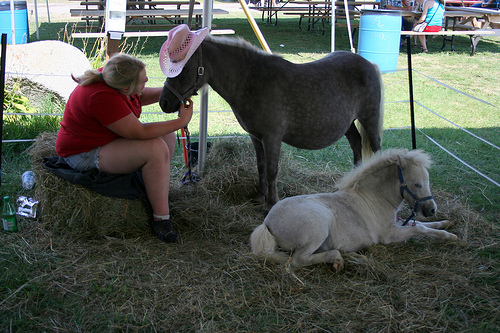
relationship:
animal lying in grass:
[250, 148, 457, 272] [80, 246, 498, 308]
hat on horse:
[156, 13, 212, 70] [190, 40, 383, 150]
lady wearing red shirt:
[54, 54, 192, 244] [69, 80, 123, 131]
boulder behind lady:
[3, 40, 91, 113] [67, 65, 161, 174]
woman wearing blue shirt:
[401, 0, 445, 52] [419, 6, 443, 24]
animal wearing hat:
[190, 46, 378, 163] [156, 24, 201, 64]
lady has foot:
[54, 54, 192, 244] [146, 204, 186, 240]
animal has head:
[261, 156, 439, 265] [369, 147, 441, 220]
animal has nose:
[250, 148, 457, 272] [406, 190, 447, 218]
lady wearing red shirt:
[61, 81, 174, 222] [66, 90, 123, 148]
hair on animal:
[208, 30, 254, 65] [180, 30, 387, 174]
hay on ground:
[115, 248, 253, 327] [11, 223, 496, 326]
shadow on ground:
[437, 131, 498, 215] [362, 27, 498, 227]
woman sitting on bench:
[415, 0, 442, 40] [401, 22, 487, 54]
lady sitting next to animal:
[54, 54, 192, 244] [159, 34, 384, 214]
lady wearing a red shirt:
[54, 54, 192, 244] [56, 67, 142, 159]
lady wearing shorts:
[54, 54, 192, 244] [58, 143, 104, 173]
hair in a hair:
[67, 55, 147, 96] [71, 53, 146, 95]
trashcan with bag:
[356, 7, 403, 76] [357, 6, 404, 17]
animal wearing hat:
[159, 34, 384, 214] [155, 21, 212, 79]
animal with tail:
[159, 34, 384, 214] [357, 62, 386, 164]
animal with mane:
[250, 148, 457, 272] [327, 144, 433, 190]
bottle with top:
[1, 193, 21, 233] [1, 190, 11, 203]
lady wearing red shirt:
[54, 54, 192, 244] [56, 67, 142, 159]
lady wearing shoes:
[54, 54, 192, 244] [146, 214, 181, 244]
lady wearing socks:
[54, 54, 192, 244] [150, 210, 174, 227]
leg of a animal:
[259, 134, 280, 218] [159, 34, 384, 214]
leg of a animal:
[342, 118, 365, 168] [159, 34, 384, 214]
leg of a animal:
[356, 103, 384, 153] [159, 34, 384, 214]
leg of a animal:
[285, 230, 347, 272] [250, 148, 457, 272]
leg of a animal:
[378, 217, 458, 247] [250, 148, 457, 272]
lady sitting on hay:
[54, 54, 192, 244] [25, 130, 151, 243]